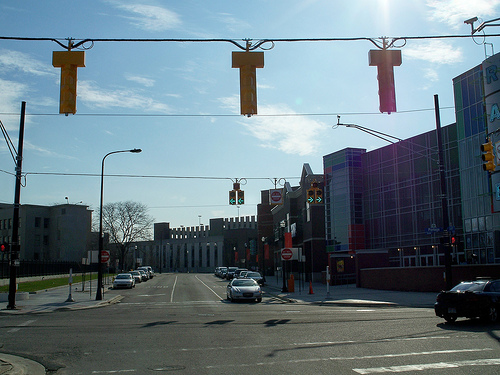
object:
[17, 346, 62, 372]
cracks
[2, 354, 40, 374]
sidewalk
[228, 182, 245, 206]
street light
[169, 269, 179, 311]
lines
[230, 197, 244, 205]
signal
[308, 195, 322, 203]
signal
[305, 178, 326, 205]
traffic signal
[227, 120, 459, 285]
building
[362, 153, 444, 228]
window panes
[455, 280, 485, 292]
windshield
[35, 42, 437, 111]
three lights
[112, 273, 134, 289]
car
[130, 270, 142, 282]
car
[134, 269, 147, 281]
car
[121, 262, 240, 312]
road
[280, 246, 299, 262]
sign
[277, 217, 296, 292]
pole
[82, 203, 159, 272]
tree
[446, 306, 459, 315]
license plate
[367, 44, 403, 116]
street light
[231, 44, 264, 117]
street light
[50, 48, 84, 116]
street light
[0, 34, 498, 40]
line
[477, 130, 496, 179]
light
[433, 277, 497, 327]
car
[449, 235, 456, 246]
hand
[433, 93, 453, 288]
pole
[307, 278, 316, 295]
cone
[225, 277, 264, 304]
car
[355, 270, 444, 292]
red paint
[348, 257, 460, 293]
wall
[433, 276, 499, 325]
black car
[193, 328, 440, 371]
lines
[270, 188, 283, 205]
sign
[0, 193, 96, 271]
building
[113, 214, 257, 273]
building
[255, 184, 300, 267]
building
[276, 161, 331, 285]
building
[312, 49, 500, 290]
building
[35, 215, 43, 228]
window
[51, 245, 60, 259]
window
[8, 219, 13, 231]
window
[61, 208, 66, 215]
window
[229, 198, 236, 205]
arrow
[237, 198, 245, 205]
arrow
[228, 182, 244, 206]
traffic light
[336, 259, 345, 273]
symbol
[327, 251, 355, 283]
wall